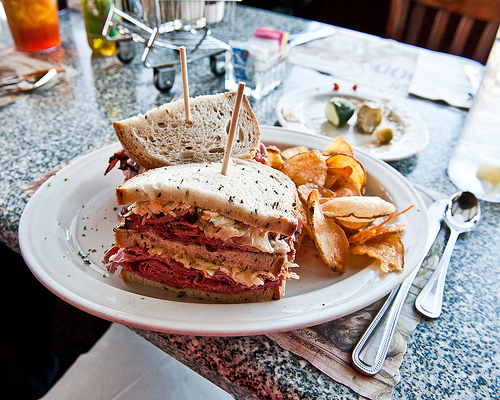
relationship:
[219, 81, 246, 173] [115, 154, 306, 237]
peg in bread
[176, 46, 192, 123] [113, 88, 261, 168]
peg in bread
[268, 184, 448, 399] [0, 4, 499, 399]
placemat on table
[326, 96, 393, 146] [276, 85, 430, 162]
food on plate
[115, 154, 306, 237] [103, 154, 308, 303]
bread on snadwich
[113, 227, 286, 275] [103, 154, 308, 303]
bread on snadwich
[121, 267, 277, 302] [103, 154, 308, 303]
bread on snadwich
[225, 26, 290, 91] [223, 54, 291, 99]
sugar packets in container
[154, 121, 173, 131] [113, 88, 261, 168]
hole in bread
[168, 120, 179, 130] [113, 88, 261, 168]
hole in bread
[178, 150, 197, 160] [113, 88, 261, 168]
hole in bread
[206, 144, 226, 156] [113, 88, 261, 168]
hole in bread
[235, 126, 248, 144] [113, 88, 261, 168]
hole in bread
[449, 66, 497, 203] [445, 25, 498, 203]
water in glass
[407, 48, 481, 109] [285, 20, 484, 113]
napkin on top of placemat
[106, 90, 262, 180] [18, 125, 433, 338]
sandwich on plate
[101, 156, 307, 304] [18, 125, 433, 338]
sandwich on plate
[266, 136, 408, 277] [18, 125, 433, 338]
potato chips on plate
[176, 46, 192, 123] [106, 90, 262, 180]
peg in sandwich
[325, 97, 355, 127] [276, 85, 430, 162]
vegetable on plate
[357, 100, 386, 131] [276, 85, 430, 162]
vegetable on plate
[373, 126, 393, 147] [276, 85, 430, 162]
vegetable on plate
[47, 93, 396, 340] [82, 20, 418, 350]
plate on table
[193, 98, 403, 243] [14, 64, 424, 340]
vegetables on plate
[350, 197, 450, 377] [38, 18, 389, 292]
butter knife on table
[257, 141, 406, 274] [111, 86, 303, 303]
chips next to sandwich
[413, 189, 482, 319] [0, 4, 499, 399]
spoon lying on table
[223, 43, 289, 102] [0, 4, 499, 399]
caddy on table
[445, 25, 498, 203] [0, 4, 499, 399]
glass on table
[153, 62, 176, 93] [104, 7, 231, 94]
wheel on cart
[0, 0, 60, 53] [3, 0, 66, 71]
tea in glass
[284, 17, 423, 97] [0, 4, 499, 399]
placemat on table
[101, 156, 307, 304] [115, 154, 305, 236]
sandwich on bread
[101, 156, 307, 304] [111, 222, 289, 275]
sandwich on bread slice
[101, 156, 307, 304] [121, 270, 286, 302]
sandwich on bread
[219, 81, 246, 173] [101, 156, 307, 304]
peg in sandwich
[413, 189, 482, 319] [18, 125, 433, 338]
spoon beside plate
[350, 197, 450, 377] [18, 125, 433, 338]
butter knife on side of plate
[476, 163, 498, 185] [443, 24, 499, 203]
lemon in water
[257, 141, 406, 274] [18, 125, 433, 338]
chips on plate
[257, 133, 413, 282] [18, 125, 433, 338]
chips on plate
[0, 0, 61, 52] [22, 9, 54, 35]
cup filled with beverage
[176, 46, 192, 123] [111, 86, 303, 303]
peg in sandwich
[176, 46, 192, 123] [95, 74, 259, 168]
peg in sandwich